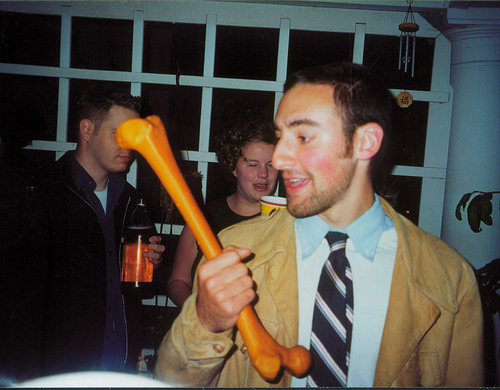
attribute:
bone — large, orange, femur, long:
[116, 115, 311, 381]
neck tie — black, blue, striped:
[311, 230, 354, 388]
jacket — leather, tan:
[152, 192, 483, 386]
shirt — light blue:
[294, 191, 400, 387]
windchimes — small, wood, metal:
[399, 2, 418, 79]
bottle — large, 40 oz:
[120, 195, 156, 298]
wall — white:
[0, 3, 457, 309]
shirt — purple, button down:
[64, 153, 127, 371]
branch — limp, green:
[454, 190, 498, 231]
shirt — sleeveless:
[188, 194, 263, 252]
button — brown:
[214, 342, 225, 353]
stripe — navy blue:
[318, 263, 348, 326]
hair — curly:
[211, 106, 277, 177]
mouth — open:
[282, 175, 313, 191]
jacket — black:
[5, 155, 157, 371]